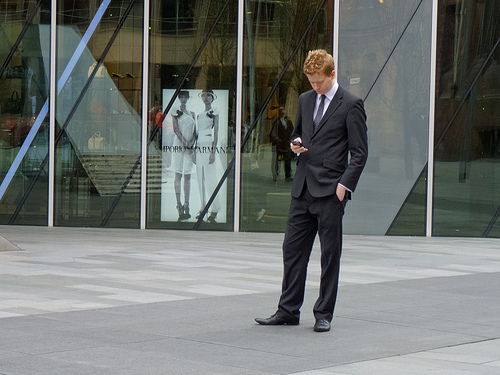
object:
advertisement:
[160, 88, 228, 224]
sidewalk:
[0, 222, 487, 369]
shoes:
[255, 306, 301, 325]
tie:
[313, 94, 327, 133]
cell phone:
[292, 141, 306, 149]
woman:
[169, 87, 196, 221]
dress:
[168, 111, 196, 175]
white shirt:
[312, 80, 339, 132]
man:
[255, 49, 367, 332]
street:
[0, 187, 500, 375]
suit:
[196, 107, 220, 212]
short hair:
[303, 50, 335, 75]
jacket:
[291, 83, 368, 199]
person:
[267, 106, 295, 183]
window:
[239, 5, 335, 233]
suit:
[276, 82, 368, 322]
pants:
[274, 185, 342, 321]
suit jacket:
[291, 84, 368, 198]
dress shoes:
[314, 318, 331, 332]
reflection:
[269, 105, 295, 182]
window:
[148, 4, 236, 227]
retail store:
[4, 1, 499, 234]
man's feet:
[255, 308, 300, 325]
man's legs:
[314, 201, 343, 321]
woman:
[194, 89, 226, 220]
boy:
[254, 49, 368, 333]